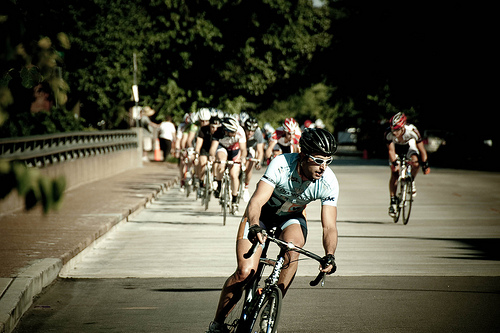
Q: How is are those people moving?
A: By pedaling their bikes.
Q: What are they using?
A: Mountain bikes.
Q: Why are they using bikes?
A: To race around the street.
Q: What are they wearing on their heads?
A: A bike helmet.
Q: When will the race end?
A: When eveyone finishes the last lap.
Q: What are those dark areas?
A: Shadows from the trees.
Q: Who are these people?
A: Professional bike riders.